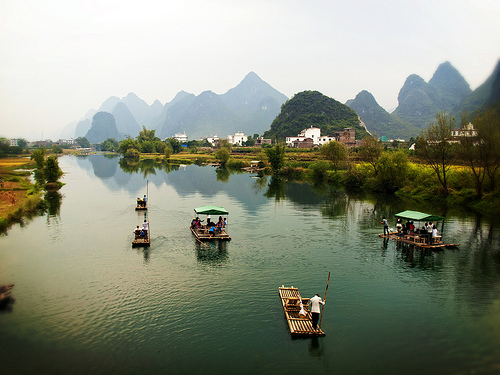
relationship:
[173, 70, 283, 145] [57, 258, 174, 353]
mountain by water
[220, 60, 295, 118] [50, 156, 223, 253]
mountain by water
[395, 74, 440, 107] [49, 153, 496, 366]
mountain peak by water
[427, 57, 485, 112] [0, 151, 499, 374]
mountain peak by river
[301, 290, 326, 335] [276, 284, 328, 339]
man on boat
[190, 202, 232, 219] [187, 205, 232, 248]
green covering on boat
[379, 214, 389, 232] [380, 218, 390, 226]
man in shirt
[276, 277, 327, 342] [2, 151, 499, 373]
boat floats on river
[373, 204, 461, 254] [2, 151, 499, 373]
boat floats on river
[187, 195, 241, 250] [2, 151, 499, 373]
boat floats on river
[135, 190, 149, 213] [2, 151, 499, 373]
boat floats on river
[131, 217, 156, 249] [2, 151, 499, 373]
boat floats on river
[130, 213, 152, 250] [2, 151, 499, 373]
boat floats along river